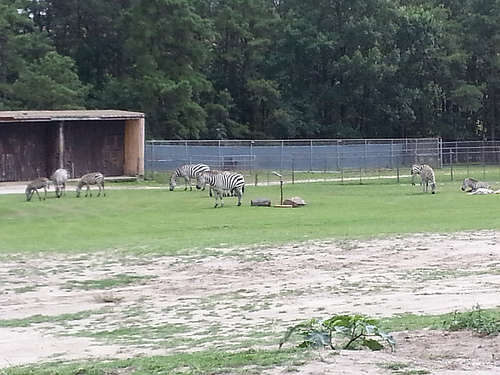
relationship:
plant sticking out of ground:
[278, 313, 394, 354] [0, 166, 495, 372]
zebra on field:
[458, 169, 499, 201] [4, 179, 497, 374]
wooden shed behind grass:
[1, 109, 148, 185] [0, 177, 497, 257]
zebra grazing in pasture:
[25, 163, 500, 208] [1, 166, 495, 253]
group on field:
[22, 150, 497, 208] [4, 179, 497, 374]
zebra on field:
[25, 163, 500, 208] [4, 179, 497, 374]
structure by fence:
[0, 107, 145, 182] [141, 133, 496, 182]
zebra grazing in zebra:
[25, 163, 500, 208] [192, 165, 246, 209]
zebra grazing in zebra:
[25, 163, 500, 208] [72, 167, 107, 199]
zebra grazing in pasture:
[25, 163, 500, 208] [0, 160, 496, 372]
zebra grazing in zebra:
[25, 163, 500, 208] [418, 164, 436, 195]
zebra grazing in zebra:
[25, 163, 500, 208] [167, 163, 209, 192]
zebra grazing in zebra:
[25, 163, 500, 208] [25, 177, 47, 203]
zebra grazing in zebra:
[25, 163, 500, 208] [51, 170, 69, 198]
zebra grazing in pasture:
[25, 163, 500, 208] [6, 182, 486, 246]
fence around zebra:
[146, 138, 500, 185] [196, 169, 245, 207]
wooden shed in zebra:
[1, 110, 146, 182] [9, 135, 372, 285]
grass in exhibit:
[0, 162, 500, 375] [0, 138, 498, 373]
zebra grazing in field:
[25, 163, 500, 208] [27, 143, 497, 239]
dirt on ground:
[14, 271, 221, 319] [3, 207, 496, 371]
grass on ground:
[14, 199, 216, 258] [3, 207, 496, 371]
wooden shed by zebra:
[1, 110, 146, 182] [72, 169, 107, 197]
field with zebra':
[2, 193, 497, 245] [173, 140, 266, 216]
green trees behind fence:
[1, 2, 496, 134] [150, 140, 495, 171]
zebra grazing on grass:
[25, 163, 500, 208] [0, 207, 498, 248]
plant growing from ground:
[278, 314, 395, 352] [0, 166, 495, 372]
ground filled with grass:
[3, 207, 496, 371] [326, 197, 454, 237]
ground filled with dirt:
[3, 207, 496, 371] [389, 295, 498, 308]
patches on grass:
[0, 220, 498, 372] [0, 310, 497, 374]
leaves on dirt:
[443, 303, 499, 338] [0, 230, 498, 375]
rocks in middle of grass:
[283, 197, 306, 207] [335, 172, 367, 212]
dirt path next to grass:
[10, 164, 415, 193] [6, 201, 496, 251]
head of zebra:
[193, 170, 207, 189] [196, 169, 245, 207]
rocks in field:
[244, 195, 319, 208] [76, 210, 221, 235]